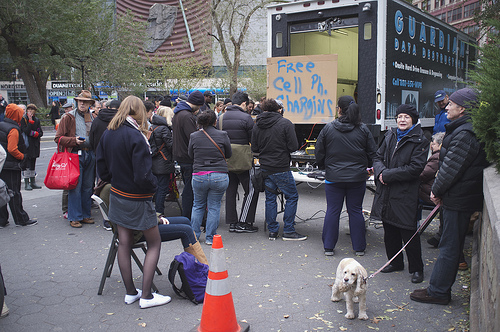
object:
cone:
[187, 233, 251, 331]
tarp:
[142, 2, 178, 52]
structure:
[115, 0, 211, 74]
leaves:
[283, 313, 288, 317]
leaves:
[314, 273, 321, 279]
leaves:
[372, 291, 377, 296]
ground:
[0, 130, 471, 331]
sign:
[265, 54, 338, 125]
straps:
[167, 259, 187, 298]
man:
[54, 89, 97, 228]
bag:
[43, 135, 80, 190]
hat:
[73, 89, 96, 104]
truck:
[265, 0, 480, 160]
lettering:
[394, 38, 417, 55]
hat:
[448, 86, 481, 108]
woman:
[96, 94, 172, 309]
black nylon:
[140, 225, 162, 299]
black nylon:
[116, 224, 138, 294]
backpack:
[168, 250, 209, 305]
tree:
[0, 0, 151, 114]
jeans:
[190, 172, 229, 243]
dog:
[330, 257, 368, 320]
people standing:
[251, 97, 307, 241]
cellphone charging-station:
[266, 0, 478, 196]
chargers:
[273, 93, 333, 123]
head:
[443, 87, 480, 120]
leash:
[368, 203, 440, 277]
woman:
[187, 111, 232, 245]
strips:
[207, 269, 229, 280]